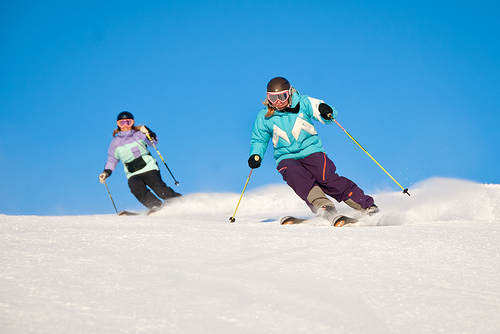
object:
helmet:
[266, 77, 290, 105]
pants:
[127, 170, 182, 217]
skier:
[88, 125, 222, 229]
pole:
[139, 125, 179, 187]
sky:
[111, 34, 202, 73]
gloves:
[246, 103, 332, 170]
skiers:
[97, 76, 382, 227]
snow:
[1, 176, 500, 305]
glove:
[246, 154, 264, 170]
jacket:
[99, 125, 158, 179]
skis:
[137, 188, 239, 225]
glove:
[97, 171, 111, 184]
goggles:
[263, 90, 301, 106]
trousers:
[276, 151, 377, 227]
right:
[236, 7, 500, 282]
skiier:
[99, 112, 184, 216]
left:
[0, 0, 207, 334]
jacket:
[248, 85, 333, 174]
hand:
[142, 135, 158, 147]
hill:
[1, 176, 500, 331]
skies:
[0, 0, 500, 214]